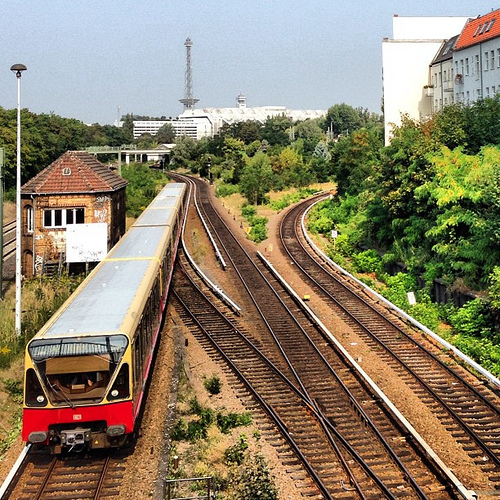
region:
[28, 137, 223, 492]
the train is in motion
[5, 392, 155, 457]
the bottom of the train is red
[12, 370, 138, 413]
the headlights are off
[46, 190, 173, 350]
the top of the train is grey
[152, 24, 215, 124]
a tower on top of the building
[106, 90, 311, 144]
a building in the background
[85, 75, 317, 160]
the building is white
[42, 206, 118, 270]
the sign is white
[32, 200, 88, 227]
the window pane is white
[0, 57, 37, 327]
the pole is tall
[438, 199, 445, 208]
part of a bush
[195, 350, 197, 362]
part of a train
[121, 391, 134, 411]
side of a train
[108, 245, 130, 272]
part of a house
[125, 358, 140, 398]
part of a train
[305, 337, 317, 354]
part of a pane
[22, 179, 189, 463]
Two car red, yellow and silver train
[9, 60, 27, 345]
Black lamp on white lightpole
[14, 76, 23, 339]
White lightpole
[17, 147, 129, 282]
Train station next to train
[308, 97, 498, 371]
Bushes next to train track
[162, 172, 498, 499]
Three differetn train tracks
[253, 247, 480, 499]
White safety railing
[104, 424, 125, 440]
Car bumper on train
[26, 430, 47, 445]
Car bumper on train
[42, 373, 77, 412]
Windshield wiper on train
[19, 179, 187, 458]
train on the railroad tracks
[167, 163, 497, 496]
railroad tracks merging into other tracks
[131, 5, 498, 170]
buildings in the background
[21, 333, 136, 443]
yellow and red front of the train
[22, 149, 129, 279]
old building next to the tracks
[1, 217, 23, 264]
railroad tracks on the other side of the building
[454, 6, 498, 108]
building with a bright orange roof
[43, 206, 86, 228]
windows in an old building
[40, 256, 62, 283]
steps going up to the old building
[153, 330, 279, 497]
grass and weeds in between the tracks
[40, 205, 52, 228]
glass window on building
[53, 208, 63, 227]
glass window on building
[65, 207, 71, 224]
glass window on building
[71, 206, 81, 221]
glass window on building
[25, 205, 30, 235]
glass window on building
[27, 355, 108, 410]
glass window on train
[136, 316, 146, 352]
glass window on train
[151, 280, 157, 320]
glass window on train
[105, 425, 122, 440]
black bumper on train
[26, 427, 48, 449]
black bumper on train